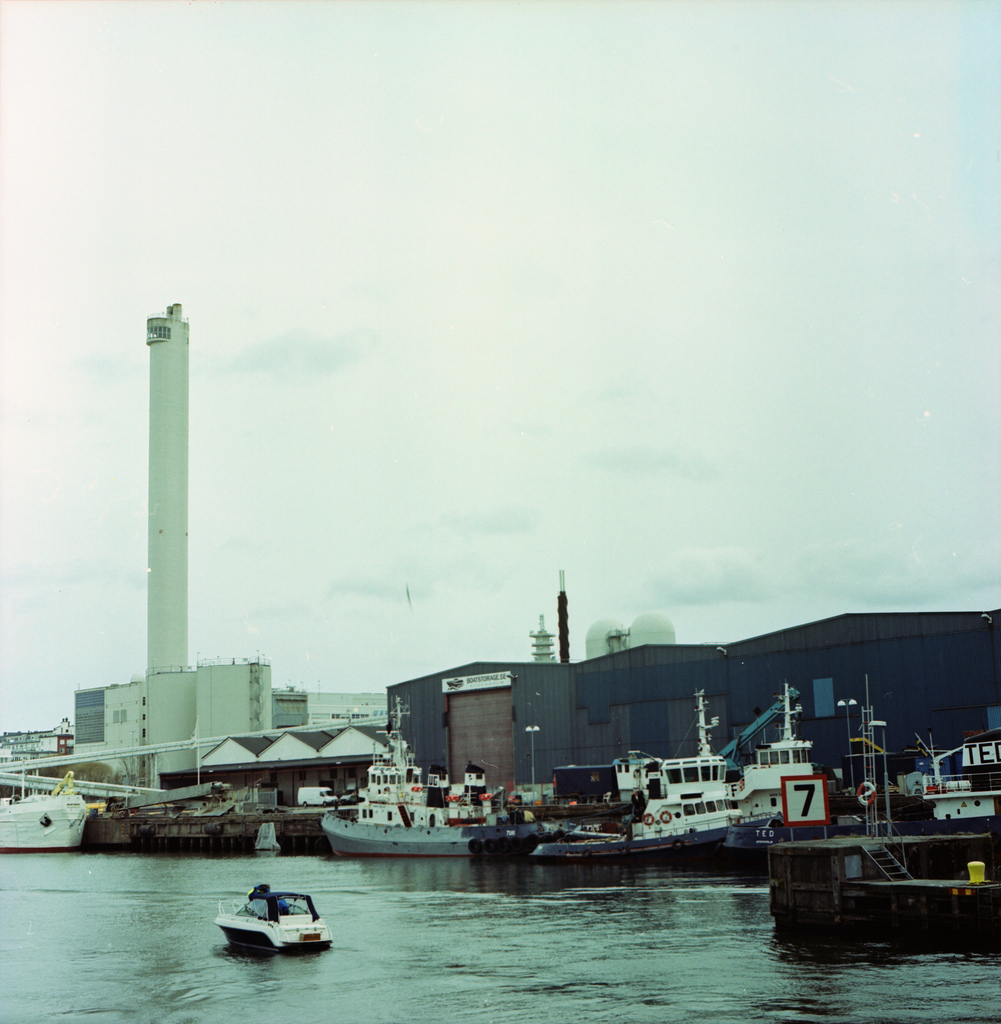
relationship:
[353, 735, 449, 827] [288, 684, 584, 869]
white top of a boat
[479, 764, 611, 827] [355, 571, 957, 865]
door on building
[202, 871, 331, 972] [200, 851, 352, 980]
window of tugboat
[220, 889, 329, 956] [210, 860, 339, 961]
window of tugboat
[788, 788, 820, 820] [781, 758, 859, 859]
number on sign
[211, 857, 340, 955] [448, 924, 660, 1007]
boat on water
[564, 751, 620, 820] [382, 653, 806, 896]
door on building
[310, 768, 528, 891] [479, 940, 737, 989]
boat on water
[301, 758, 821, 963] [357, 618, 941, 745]
ship mocked building